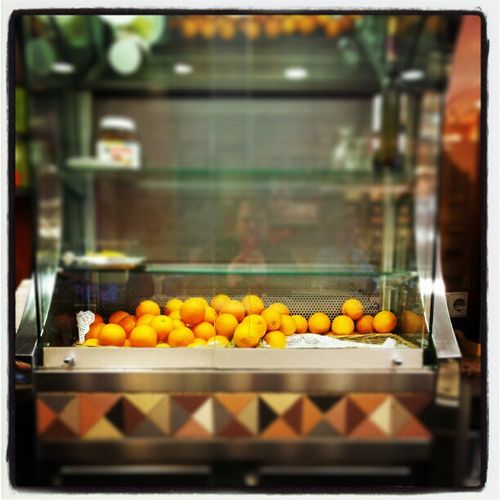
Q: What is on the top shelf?
A: Nutella.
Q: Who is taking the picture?
A: Man.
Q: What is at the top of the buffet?
A: Mirror.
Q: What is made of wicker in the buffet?
A: Basket.